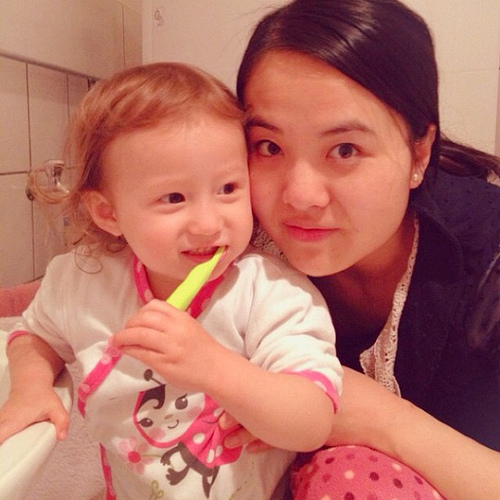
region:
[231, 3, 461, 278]
Asian woman's face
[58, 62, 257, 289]
Baby's face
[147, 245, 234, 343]
Toothbrush used by child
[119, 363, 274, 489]
ladybug character on child's clothing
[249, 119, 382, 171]
Asian woman's eyes and brows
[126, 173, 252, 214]
Child's eyes and eyebrows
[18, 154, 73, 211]
Faucet in the background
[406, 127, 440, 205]
Asian woman's ear with earring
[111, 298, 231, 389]
Child's hand holding the toothbrush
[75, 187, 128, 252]
Child's right ear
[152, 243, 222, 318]
the little girl brushing her teeth with a toothbrush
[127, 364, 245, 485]
the ladybug picture on the shirt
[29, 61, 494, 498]
a little girl standing in the bathroom with her mom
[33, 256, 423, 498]
the pajamas the girl is wearing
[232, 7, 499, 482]
the little girls mother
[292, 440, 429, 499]
the polka dots on the pants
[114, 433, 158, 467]
the flower the ladybug is wearing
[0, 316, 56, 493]
the edge of the sink that the girl is holding onto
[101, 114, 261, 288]
the happy face of the little girl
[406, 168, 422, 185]
the pearl earring in the mom's ear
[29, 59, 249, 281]
the toddler has red hair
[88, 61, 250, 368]
the toddler is brushing her teeth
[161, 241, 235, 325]
the toothbrush in her is yellow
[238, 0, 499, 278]
the lady has long dark hair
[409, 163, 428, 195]
a pearl earring is in the lady's ear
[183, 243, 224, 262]
the little girl has baby teeth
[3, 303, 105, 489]
a hand is on the bathroom sink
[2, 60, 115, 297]
tile is on the wall of the bathroom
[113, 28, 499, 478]
the woman is holding the toddler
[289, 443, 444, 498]
pink polka dots are on the pants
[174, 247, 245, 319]
Green toothbrush in baby's mouth.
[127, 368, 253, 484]
Lady bug on a baby's shirt.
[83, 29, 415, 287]
Woman and baby face.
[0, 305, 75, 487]
Baby holding on to the sink.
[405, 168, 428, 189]
Pearl earring in woman's ear.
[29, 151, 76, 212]
Towel shelf in bathroom.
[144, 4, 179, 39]
Picture on bathroom wall.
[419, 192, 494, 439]
Blue blazer on woman.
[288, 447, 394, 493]
Pink polka dot baby pants.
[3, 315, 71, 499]
Edge of white bathtub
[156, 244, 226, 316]
Yellow handle of toothbrush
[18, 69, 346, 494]
Small girl brushing teeth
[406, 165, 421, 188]
Stud earring on woman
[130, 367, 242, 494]
Ladybug design on girl's shirt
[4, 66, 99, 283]
Tile on bathroom wall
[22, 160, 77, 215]
Soap dish mounted on wall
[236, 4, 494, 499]
Black haired woman holding child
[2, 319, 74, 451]
Girl's hand on bathtub rim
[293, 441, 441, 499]
Pink polka dot pants